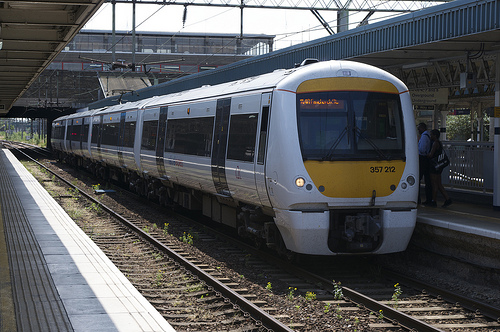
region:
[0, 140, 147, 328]
tiled and concrete platform for a train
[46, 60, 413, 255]
a white passenger train with a yellow area for the windshield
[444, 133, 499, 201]
a gate to the far platform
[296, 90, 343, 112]
destination of this train route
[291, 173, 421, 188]
one headlight is lit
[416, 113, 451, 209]
people wait to board the train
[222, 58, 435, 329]
a train on the tracks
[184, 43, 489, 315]
a white and yellow train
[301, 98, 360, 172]
a train with window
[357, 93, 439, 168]
a train with window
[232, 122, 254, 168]
a train with window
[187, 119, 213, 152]
a train with window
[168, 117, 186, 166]
a train with window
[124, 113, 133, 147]
a train with window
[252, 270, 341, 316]
tiny green trees in middle of track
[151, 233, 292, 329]
dark train tracks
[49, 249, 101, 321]
blue color on platform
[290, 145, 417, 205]
yellow color in front of train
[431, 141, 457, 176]
stripe bag around woman's shoulders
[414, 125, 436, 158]
man wearing blue shirt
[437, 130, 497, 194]
white fence on the platform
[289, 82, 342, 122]
The orange writing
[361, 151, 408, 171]
The numbers on the front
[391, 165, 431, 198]
The headlight that is not on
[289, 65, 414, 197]
The face of the car is yellow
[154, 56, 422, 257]
The first car of the train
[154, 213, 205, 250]
There are plants growing from the tracks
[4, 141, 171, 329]
The part of the platform that is not shaded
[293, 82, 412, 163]
The windshield of the train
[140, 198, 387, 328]
weeds in the track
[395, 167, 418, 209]
the light is out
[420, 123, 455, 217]
people on the platform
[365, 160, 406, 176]
the numbers are black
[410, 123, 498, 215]
gate behind the people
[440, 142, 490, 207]
the gate is white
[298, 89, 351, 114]
the lettering is orange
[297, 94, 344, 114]
the lettering on the screen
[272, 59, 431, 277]
Train has a yellow and white front on it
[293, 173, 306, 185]
Train has one light lit up on the front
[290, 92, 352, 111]
Digital sign shows the location the bus is going to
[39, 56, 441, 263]
Transport vehicle is a passenger train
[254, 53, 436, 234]
Numbers on the front of the train engine on the car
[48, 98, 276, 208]
Doors on the side of the train in the yard.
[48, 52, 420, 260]
A modern train at a train stop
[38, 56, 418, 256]
A white train with a yellow front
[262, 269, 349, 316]
Small green plants growing on the train tracks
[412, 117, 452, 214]
People waiting at the train stop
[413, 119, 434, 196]
A man in a blue shirt standing next to a person dressed in black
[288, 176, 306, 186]
One light on the train front lit up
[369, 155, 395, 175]
Black numbers printed on the front of a train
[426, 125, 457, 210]
A person carrying a black bag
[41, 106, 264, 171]
Large windows on the side of the white train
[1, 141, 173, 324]
A platform to the left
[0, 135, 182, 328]
The platform to the left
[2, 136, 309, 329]
The empty train track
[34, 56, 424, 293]
The train at the station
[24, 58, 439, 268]
A yellow and white train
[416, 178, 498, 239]
The subway platform to the right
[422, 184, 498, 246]
A subway platform to the right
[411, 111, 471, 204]
the people on the platform